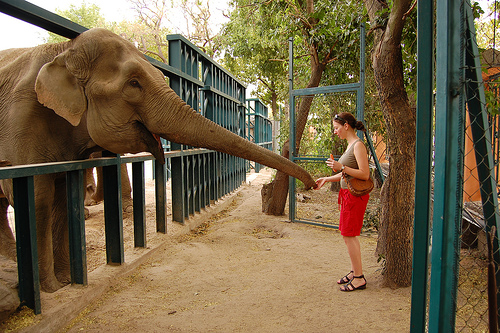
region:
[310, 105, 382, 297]
a woman touching an elephant's trunk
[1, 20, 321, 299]
an elephant reaching it's trunk out to a woman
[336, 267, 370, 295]
black sandals with straps on them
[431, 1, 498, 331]
a chain link fence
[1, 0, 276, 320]
green metal bars separating the elephant from the woman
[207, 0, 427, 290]
two trees behind the woman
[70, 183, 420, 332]
a ground made of dirt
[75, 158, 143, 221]
legs of another elephant standing behind the first elephant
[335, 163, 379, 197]
a brown purse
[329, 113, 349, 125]
a pair of black sunglasses on the woman's head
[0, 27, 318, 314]
elephant standing in the dirt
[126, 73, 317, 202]
trunk extended out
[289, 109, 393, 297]
woman touching the end of the trunk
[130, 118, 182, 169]
mouth is open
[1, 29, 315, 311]
elephant standing behind a fence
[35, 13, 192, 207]
head sticking through the poles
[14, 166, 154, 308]
row of four small posts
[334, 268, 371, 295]
a pair of black sandals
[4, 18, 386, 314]
woman feedin an elephant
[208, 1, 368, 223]
tree that is leaning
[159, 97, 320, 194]
an elephants trunk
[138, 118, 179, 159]
the open mouth of an elephant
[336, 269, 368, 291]
womans brown sandles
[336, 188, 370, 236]
woman's red shorts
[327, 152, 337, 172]
a long orange carrot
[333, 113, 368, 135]
a womans brown hair in a bun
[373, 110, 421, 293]
the trunk of a brown tree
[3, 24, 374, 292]
a woman feeding carrots to an elephant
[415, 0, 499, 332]
part of a green fence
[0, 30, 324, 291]
a big grey elephant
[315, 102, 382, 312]
lady at the zoo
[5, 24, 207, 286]
elephant behind a fence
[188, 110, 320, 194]
trunk of the elephant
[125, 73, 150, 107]
eye of the elephant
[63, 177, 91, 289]
beam on the fence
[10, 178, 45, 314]
beam on the fence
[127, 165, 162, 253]
beam on the fence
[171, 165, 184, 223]
beam on the fence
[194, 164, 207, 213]
beam on the fence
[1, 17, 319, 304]
elephant with outstretched trunk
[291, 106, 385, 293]
woman touching elephant's trunk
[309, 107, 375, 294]
woman with brown hair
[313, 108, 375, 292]
woman wearing brown sandals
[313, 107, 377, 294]
woman wearing brown tank top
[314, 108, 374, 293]
woman carrying brown purse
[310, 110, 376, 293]
woman wearing red shorts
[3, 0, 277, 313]
blue metal fence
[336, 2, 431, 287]
tree behind the woman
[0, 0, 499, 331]
scene at the zoo